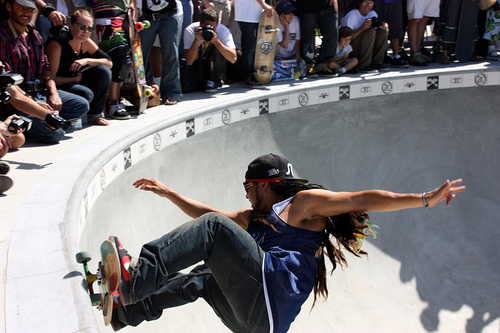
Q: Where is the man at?
A: Skateboard park.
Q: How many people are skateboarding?
A: One.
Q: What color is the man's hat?
A: Black.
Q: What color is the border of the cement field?
A: White.